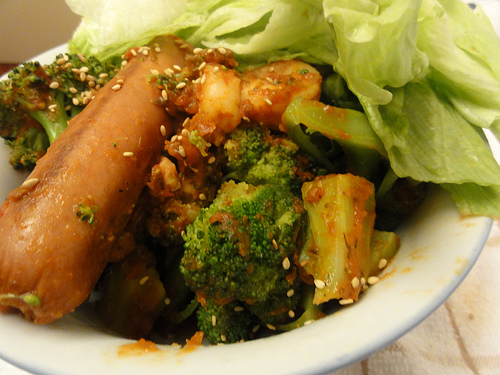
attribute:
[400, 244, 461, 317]
plate — white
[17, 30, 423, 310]
vegetable — cooked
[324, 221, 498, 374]
table cloth — white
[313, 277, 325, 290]
seed — small, white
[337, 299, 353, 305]
seed — small, white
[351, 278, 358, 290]
seed — small, white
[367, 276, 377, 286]
seed — small, white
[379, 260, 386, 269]
seed — small, white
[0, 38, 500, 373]
white bowl — round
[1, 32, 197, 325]
carrot — cooked, orange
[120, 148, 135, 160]
seed — sesame, tiny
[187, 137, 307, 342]
zebra — hunk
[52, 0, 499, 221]
lettuce — green, iceberg, leaf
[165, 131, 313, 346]
broccoli — cooked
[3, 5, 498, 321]
vegetable — long, brown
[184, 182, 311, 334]
broccoli — cooked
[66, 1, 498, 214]
cabbage — light green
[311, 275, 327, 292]
seed — white, sesame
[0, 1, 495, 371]
bowl — shallow, white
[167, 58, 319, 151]
potatoes — cooked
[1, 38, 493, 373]
bowl — white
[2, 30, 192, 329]
meat — cooked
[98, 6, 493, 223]
lettuce — light green, leafy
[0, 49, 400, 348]
broccoi — green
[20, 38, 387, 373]
seeds — cooked